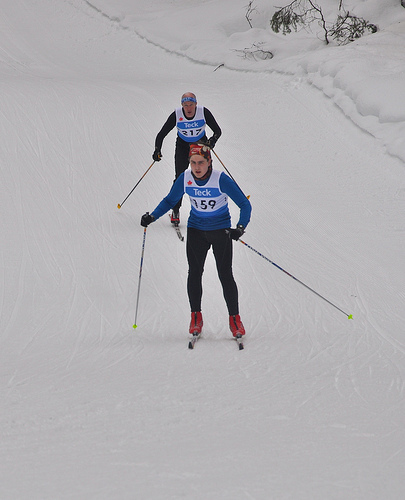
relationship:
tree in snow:
[235, 10, 352, 86] [249, 60, 328, 122]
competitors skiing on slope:
[107, 52, 279, 376] [64, 61, 373, 387]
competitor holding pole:
[107, 52, 279, 376] [110, 188, 161, 346]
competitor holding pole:
[110, 154, 301, 344] [110, 188, 161, 346]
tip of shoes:
[177, 334, 206, 359] [185, 312, 206, 338]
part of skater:
[181, 300, 218, 351] [110, 154, 301, 344]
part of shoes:
[181, 300, 218, 351] [156, 312, 239, 356]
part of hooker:
[181, 300, 218, 351] [149, 267, 228, 358]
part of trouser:
[181, 300, 218, 351] [165, 246, 224, 290]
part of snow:
[283, 30, 323, 93] [249, 60, 328, 122]